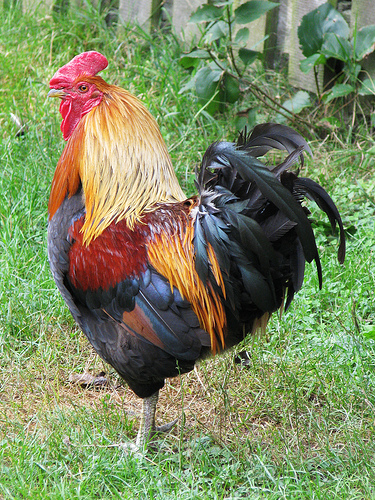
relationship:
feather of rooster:
[189, 123, 343, 356] [44, 49, 345, 466]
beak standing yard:
[46, 88, 66, 99] [5, 6, 363, 498]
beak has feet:
[46, 88, 66, 99] [92, 369, 213, 465]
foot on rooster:
[109, 439, 147, 468] [34, 62, 270, 402]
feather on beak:
[189, 123, 343, 356] [46, 88, 66, 99]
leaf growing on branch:
[191, 59, 229, 99] [200, 42, 319, 131]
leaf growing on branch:
[246, 102, 260, 125] [236, 85, 315, 140]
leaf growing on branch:
[188, 3, 223, 23] [225, 5, 244, 78]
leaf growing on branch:
[296, 2, 351, 55] [312, 62, 321, 100]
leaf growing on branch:
[324, 79, 356, 102] [347, 81, 358, 145]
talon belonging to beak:
[152, 420, 181, 449] [46, 88, 66, 99]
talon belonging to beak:
[110, 439, 150, 471] [46, 88, 66, 99]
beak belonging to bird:
[46, 88, 66, 99] [39, 57, 351, 458]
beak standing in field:
[46, 88, 66, 99] [5, 14, 363, 496]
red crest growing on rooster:
[42, 41, 110, 90] [31, 35, 357, 481]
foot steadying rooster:
[152, 420, 178, 441] [36, 55, 322, 373]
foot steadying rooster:
[109, 439, 147, 468] [36, 55, 322, 373]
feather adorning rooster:
[198, 138, 321, 283] [44, 49, 345, 466]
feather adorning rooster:
[189, 123, 343, 356] [44, 49, 345, 466]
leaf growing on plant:
[319, 32, 352, 65] [182, 1, 362, 145]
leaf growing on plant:
[349, 22, 374, 66] [182, 1, 362, 145]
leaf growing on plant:
[175, 66, 226, 112] [182, 1, 362, 145]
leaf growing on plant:
[230, 7, 269, 24] [182, 1, 362, 145]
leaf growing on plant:
[177, 48, 216, 71] [182, 1, 362, 145]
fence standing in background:
[0, 1, 372, 131] [1, 1, 362, 161]